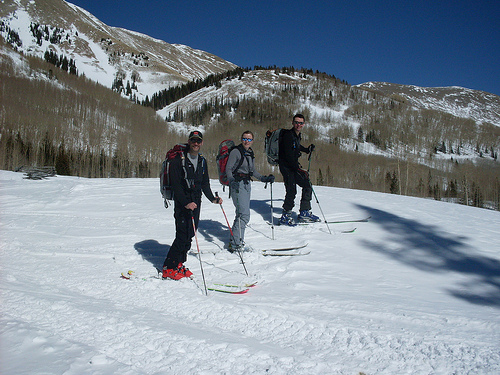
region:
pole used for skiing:
[186, 212, 211, 294]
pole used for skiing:
[214, 190, 251, 276]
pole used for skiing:
[266, 175, 278, 235]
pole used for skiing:
[307, 173, 330, 233]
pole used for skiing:
[302, 152, 312, 172]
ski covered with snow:
[115, 269, 248, 295]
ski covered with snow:
[126, 269, 260, 288]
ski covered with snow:
[170, 246, 310, 257]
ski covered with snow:
[258, 243, 305, 250]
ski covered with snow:
[264, 219, 356, 236]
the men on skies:
[122, 99, 373, 293]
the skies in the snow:
[113, 271, 264, 298]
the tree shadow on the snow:
[356, 196, 498, 314]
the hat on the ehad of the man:
[184, 127, 205, 156]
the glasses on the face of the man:
[239, 129, 256, 152]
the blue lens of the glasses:
[239, 135, 252, 144]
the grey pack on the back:
[262, 124, 284, 168]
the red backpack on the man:
[211, 134, 233, 186]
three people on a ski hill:
[156, 112, 329, 278]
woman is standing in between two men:
[219, 128, 259, 253]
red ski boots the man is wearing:
[161, 262, 194, 282]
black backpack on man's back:
[265, 125, 283, 163]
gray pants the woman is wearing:
[224, 179, 251, 250]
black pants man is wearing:
[168, 197, 199, 265]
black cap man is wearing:
[188, 129, 203, 143]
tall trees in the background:
[131, 66, 351, 113]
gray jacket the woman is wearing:
[226, 146, 264, 186]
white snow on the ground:
[1, 172, 497, 372]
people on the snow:
[120, 97, 325, 270]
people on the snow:
[111, 84, 333, 284]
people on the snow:
[105, 90, 347, 308]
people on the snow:
[141, 78, 335, 316]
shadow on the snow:
[344, 180, 487, 332]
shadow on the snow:
[338, 181, 490, 361]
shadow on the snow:
[341, 198, 493, 338]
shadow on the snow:
[355, 190, 483, 335]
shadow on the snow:
[354, 187, 498, 339]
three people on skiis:
[155, 95, 343, 305]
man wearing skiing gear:
[134, 108, 245, 305]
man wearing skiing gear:
[209, 126, 289, 276]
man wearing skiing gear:
[264, 103, 360, 230]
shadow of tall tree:
[372, 202, 497, 366]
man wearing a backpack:
[261, 122, 311, 180]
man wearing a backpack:
[218, 141, 260, 195]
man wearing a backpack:
[160, 139, 213, 229]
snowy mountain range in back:
[2, 2, 204, 182]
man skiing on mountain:
[146, 116, 216, 297]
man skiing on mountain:
[226, 123, 273, 262]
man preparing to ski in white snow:
[163, 121, 216, 302]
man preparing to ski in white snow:
[278, 96, 323, 218]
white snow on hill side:
[58, 300, 104, 330]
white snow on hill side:
[229, 336, 277, 366]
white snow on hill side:
[315, 298, 368, 337]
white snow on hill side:
[58, 228, 103, 273]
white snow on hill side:
[405, 232, 442, 276]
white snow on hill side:
[104, 199, 126, 219]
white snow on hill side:
[80, 318, 111, 345]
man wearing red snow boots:
[163, 125, 206, 285]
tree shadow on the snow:
[355, 195, 498, 305]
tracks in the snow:
[9, 189, 489, 374]